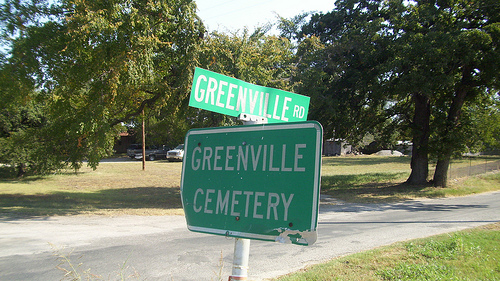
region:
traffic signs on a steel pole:
[153, 52, 333, 279]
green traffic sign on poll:
[181, 120, 327, 250]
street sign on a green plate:
[180, 122, 325, 248]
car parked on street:
[161, 142, 188, 163]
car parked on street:
[134, 141, 169, 161]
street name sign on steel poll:
[190, 65, 317, 128]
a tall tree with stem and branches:
[291, 4, 498, 194]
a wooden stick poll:
[130, 65, 152, 173]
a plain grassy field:
[9, 137, 180, 219]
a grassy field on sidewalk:
[270, 217, 497, 275]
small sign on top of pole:
[180, 63, 317, 133]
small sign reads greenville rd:
[184, 56, 316, 137]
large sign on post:
[173, 120, 326, 252]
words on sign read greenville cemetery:
[184, 140, 307, 229]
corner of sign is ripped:
[269, 217, 324, 249]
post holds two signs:
[223, 232, 253, 279]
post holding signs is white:
[220, 233, 256, 280]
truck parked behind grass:
[136, 138, 171, 168]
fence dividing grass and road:
[442, 149, 499, 183]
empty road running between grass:
[3, 188, 497, 277]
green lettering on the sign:
[189, 139, 316, 228]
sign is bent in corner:
[175, 197, 199, 241]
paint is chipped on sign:
[271, 222, 311, 243]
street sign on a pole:
[179, 75, 306, 117]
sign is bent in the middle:
[178, 73, 318, 125]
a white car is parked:
[170, 144, 183, 164]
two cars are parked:
[128, 143, 180, 163]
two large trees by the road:
[328, 36, 498, 190]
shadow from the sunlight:
[328, 173, 485, 217]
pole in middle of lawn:
[129, 85, 154, 184]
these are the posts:
[175, 78, 312, 234]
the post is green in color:
[208, 116, 311, 216]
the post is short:
[177, 75, 316, 228]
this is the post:
[228, 232, 254, 279]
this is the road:
[93, 216, 164, 253]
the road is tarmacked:
[103, 223, 180, 268]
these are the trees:
[404, 68, 461, 188]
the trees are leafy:
[383, 3, 461, 93]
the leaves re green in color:
[366, 8, 459, 80]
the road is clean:
[110, 211, 174, 264]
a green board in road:
[184, 68, 334, 133]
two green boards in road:
[153, 62, 335, 254]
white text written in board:
[187, 105, 333, 238]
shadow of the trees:
[357, 184, 492, 249]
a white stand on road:
[219, 244, 271, 277]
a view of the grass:
[323, 223, 495, 270]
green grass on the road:
[314, 239, 491, 273]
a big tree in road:
[326, 0, 491, 257]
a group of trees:
[20, 18, 495, 176]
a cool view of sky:
[207, 1, 350, 68]